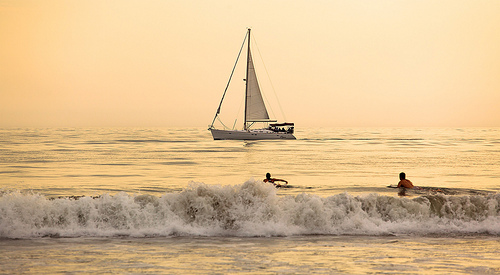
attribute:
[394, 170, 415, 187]
person — swimming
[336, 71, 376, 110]
sky — yellow, with no clouds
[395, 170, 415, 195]
person — swimming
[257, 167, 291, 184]
person — swimming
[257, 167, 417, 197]
people — very wet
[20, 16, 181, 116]
sky clouds — with no clouds, yellow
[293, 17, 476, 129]
sky clouds — yellow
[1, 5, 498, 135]
sky — yellow, with no clouds, no clouds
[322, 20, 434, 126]
sky — with no clouds, yellow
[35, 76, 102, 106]
sky — yellow, with no clouds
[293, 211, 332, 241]
badsentence — no clouds